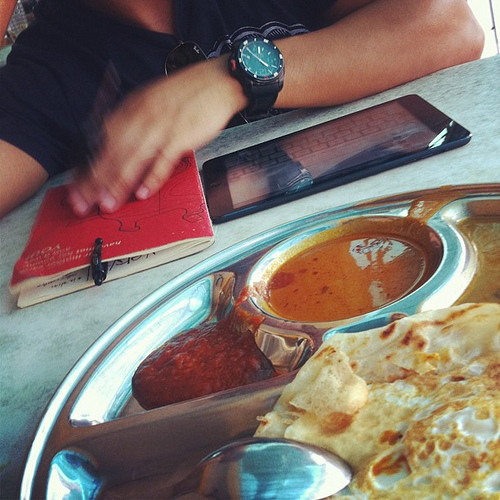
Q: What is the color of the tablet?
A: Black.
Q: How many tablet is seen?
A: 1.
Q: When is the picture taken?
A: Daytime.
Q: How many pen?
A: 1.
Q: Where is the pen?
A: In the book.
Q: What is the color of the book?
A: Red.